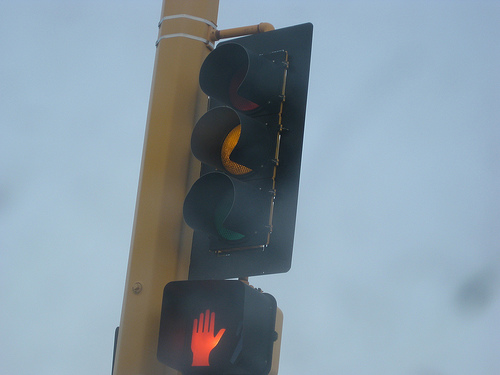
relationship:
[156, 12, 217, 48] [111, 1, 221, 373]
white straps on pole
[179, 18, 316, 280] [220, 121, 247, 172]
frame on lights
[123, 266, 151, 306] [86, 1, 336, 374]
bolt on pole